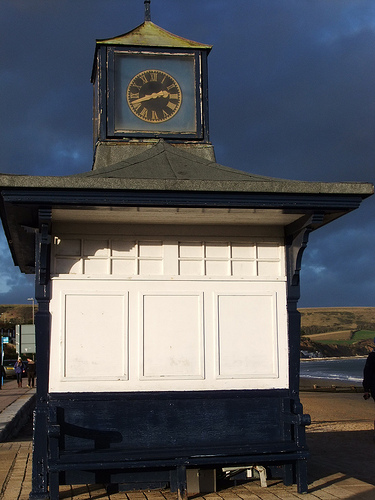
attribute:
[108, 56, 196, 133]
clock — black, brown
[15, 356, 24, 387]
person — walking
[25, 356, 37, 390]
person — walking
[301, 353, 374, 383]
water — here, blue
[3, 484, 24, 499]
brick — here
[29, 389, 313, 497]
bench — scene, black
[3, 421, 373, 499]
floor — brown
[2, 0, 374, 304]
sky — blue, here, dull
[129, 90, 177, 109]
time — 2.43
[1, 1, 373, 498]
picture — daytime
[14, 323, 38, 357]
back — sign, blue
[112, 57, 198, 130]
skating — blue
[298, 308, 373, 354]
mountain — dry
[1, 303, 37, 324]
grass — green